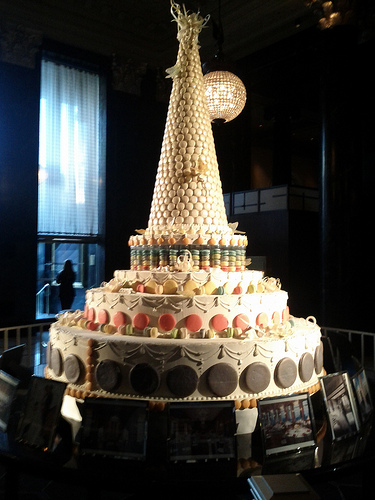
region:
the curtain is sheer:
[46, 93, 104, 227]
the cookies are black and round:
[204, 352, 329, 392]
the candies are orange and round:
[177, 314, 251, 334]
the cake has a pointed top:
[122, 11, 254, 225]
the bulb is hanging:
[213, 58, 255, 125]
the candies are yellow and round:
[158, 276, 216, 297]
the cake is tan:
[199, 342, 257, 364]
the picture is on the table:
[252, 391, 324, 460]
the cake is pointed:
[2, 3, 338, 407]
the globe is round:
[204, 53, 251, 124]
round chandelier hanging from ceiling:
[203, 6, 246, 122]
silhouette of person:
[57, 261, 77, 309]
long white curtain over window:
[42, 54, 98, 232]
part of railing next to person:
[36, 282, 50, 318]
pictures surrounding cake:
[0, 335, 371, 461]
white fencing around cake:
[0, 322, 373, 375]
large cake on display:
[47, 4, 324, 399]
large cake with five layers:
[46, 2, 324, 398]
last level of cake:
[45, 331, 322, 396]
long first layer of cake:
[148, 6, 231, 230]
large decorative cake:
[31, 2, 331, 404]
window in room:
[37, 60, 107, 241]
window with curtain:
[40, 56, 104, 239]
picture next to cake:
[321, 372, 360, 447]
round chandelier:
[203, 67, 245, 124]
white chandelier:
[202, 69, 247, 121]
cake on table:
[49, 2, 320, 395]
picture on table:
[253, 394, 319, 457]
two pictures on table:
[84, 398, 242, 467]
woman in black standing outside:
[55, 258, 75, 311]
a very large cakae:
[39, 18, 330, 415]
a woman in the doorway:
[38, 252, 86, 328]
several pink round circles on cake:
[84, 301, 294, 335]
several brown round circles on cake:
[37, 345, 332, 390]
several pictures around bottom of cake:
[0, 368, 374, 471]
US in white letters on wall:
[234, 186, 314, 218]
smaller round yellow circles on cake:
[122, 272, 274, 292]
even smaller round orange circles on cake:
[142, 232, 250, 247]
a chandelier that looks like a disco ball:
[197, 63, 250, 125]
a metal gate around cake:
[3, 310, 374, 368]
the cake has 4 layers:
[0, 0, 370, 429]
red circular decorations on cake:
[72, 303, 291, 331]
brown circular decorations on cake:
[21, 332, 365, 391]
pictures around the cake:
[48, 384, 368, 462]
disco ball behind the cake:
[191, 60, 263, 130]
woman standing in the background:
[48, 254, 86, 308]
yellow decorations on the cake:
[117, 260, 258, 315]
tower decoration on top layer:
[134, 9, 241, 246]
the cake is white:
[34, 5, 330, 409]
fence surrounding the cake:
[2, 302, 372, 458]